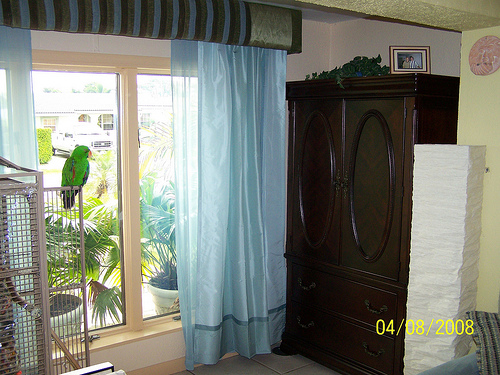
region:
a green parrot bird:
[57, 142, 89, 209]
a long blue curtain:
[162, 35, 284, 360]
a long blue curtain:
[0, 34, 34, 372]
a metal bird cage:
[0, 151, 100, 370]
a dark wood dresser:
[286, 68, 448, 365]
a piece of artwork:
[465, 34, 499, 79]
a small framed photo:
[385, 44, 432, 77]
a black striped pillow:
[466, 306, 497, 372]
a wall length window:
[132, 69, 192, 319]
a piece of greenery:
[291, 56, 388, 81]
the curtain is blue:
[169, 119, 299, 311]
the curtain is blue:
[231, 94, 261, 339]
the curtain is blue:
[237, 267, 264, 371]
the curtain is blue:
[214, 219, 294, 352]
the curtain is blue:
[245, 153, 311, 333]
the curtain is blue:
[274, 282, 307, 365]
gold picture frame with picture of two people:
[352, 33, 464, 90]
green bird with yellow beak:
[45, 142, 105, 218]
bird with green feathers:
[45, 135, 131, 212]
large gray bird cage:
[0, 148, 91, 372]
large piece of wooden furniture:
[245, 73, 469, 363]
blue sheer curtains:
[172, 39, 301, 366]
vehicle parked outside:
[45, 104, 124, 164]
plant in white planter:
[129, 179, 196, 329]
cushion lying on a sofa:
[452, 303, 495, 373]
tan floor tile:
[199, 346, 296, 372]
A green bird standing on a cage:
[53, 131, 97, 220]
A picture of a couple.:
[390, 48, 432, 74]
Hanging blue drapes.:
[170, 38, 296, 358]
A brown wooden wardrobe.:
[290, 82, 413, 369]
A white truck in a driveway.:
[51, 123, 115, 146]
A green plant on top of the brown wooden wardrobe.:
[308, 54, 392, 79]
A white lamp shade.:
[405, 143, 480, 304]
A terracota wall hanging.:
[463, 37, 498, 77]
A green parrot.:
[62, 141, 94, 183]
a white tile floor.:
[232, 357, 315, 371]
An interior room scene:
[9, 22, 498, 363]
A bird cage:
[4, 178, 99, 373]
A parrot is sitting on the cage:
[54, 142, 102, 216]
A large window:
[26, 50, 213, 340]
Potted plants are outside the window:
[48, 181, 185, 326]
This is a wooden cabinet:
[280, 71, 425, 369]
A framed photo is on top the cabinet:
[385, 37, 441, 92]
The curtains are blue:
[161, 37, 288, 365]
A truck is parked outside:
[50, 110, 121, 157]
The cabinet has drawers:
[278, 264, 408, 364]